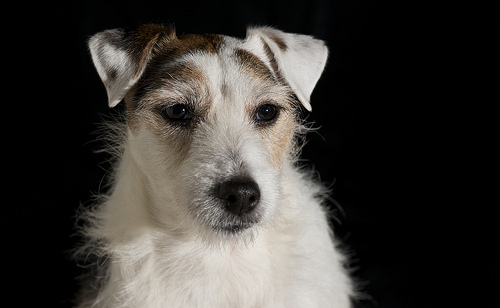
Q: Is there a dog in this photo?
A: Yes, there is a dog.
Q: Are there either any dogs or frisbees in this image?
A: Yes, there is a dog.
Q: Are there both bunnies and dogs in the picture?
A: No, there is a dog but no bunnies.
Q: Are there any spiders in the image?
A: No, there are no spiders.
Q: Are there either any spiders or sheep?
A: No, there are no spiders or sheep.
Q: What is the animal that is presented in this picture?
A: The animal is a dog.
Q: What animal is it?
A: The animal is a dog.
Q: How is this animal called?
A: That is a dog.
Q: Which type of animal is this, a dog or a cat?
A: That is a dog.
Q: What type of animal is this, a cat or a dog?
A: That is a dog.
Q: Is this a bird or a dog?
A: This is a dog.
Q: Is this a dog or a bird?
A: This is a dog.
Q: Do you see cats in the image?
A: No, there are no cats.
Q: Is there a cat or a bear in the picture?
A: No, there are no cats or bears.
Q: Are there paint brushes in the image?
A: No, there are no paint brushes.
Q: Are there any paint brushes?
A: No, there are no paint brushes.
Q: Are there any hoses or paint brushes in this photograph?
A: No, there are no paint brushes or hoses.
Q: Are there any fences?
A: No, there are no fences.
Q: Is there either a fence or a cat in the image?
A: No, there are no fences or cats.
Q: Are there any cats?
A: No, there are no cats.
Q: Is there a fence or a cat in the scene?
A: No, there are no cats or fences.